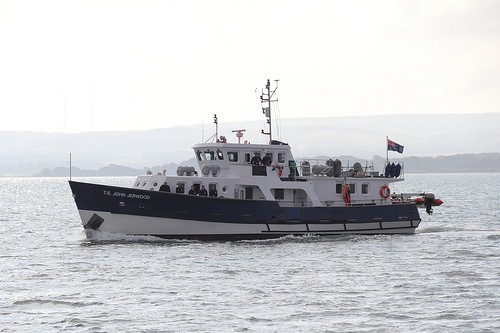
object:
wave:
[9, 292, 104, 314]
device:
[379, 185, 390, 198]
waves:
[378, 261, 473, 321]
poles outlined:
[61, 95, 70, 135]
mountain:
[1, 127, 185, 175]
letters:
[103, 190, 150, 199]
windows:
[208, 183, 216, 191]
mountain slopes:
[390, 113, 497, 156]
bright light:
[75, 9, 323, 79]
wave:
[225, 269, 306, 310]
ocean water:
[291, 251, 448, 313]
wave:
[15, 290, 102, 312]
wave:
[443, 242, 498, 261]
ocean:
[18, 222, 495, 314]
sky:
[1, 1, 498, 141]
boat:
[66, 79, 421, 244]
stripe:
[176, 210, 192, 215]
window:
[349, 184, 357, 194]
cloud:
[62, 39, 232, 89]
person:
[250, 152, 263, 165]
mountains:
[89, 164, 138, 178]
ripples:
[428, 221, 492, 252]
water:
[0, 171, 499, 332]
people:
[160, 181, 217, 197]